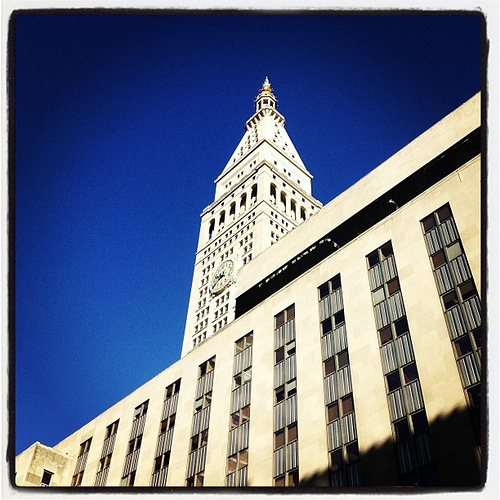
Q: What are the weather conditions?
A: It is clear.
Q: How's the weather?
A: It is clear.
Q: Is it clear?
A: Yes, it is clear.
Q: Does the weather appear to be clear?
A: Yes, it is clear.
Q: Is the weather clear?
A: Yes, it is clear.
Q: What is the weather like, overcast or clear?
A: It is clear.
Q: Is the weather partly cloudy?
A: No, it is clear.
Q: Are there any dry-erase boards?
A: No, there are no dry-erase boards.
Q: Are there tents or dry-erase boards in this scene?
A: No, there are no dry-erase boards or tents.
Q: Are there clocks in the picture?
A: Yes, there is a clock.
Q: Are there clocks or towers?
A: Yes, there is a clock.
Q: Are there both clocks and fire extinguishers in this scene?
A: No, there is a clock but no fire extinguishers.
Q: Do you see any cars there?
A: No, there are no cars.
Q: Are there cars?
A: No, there are no cars.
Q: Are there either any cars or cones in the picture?
A: No, there are no cars or cones.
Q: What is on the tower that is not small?
A: The clock is on the tower.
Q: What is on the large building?
A: The clock is on the tower.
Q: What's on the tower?
A: The clock is on the tower.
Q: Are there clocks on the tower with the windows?
A: Yes, there is a clock on the tower.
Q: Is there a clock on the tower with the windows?
A: Yes, there is a clock on the tower.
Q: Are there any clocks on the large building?
A: Yes, there is a clock on the tower.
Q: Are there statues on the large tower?
A: No, there is a clock on the tower.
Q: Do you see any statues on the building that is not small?
A: No, there is a clock on the tower.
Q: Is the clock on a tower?
A: Yes, the clock is on a tower.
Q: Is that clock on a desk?
A: No, the clock is on a tower.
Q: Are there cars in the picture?
A: No, there are no cars.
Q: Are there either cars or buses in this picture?
A: No, there are no cars or buses.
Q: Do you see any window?
A: Yes, there are windows.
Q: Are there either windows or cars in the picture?
A: Yes, there are windows.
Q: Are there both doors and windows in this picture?
A: No, there are windows but no doors.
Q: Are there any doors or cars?
A: No, there are no cars or doors.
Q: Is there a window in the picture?
A: Yes, there are windows.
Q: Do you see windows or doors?
A: Yes, there are windows.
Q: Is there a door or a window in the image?
A: Yes, there are windows.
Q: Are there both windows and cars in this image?
A: No, there are windows but no cars.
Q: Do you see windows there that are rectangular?
A: Yes, there are rectangular windows.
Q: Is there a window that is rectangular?
A: Yes, there are windows that are rectangular.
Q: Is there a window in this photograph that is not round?
A: Yes, there are rectangular windows.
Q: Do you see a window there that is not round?
A: Yes, there are rectangular windows.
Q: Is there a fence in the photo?
A: No, there are no fences.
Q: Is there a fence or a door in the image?
A: No, there are no fences or doors.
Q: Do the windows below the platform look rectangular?
A: Yes, the windows are rectangular.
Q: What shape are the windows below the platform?
A: The windows are rectangular.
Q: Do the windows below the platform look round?
A: No, the windows are rectangular.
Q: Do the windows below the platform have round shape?
A: No, the windows are rectangular.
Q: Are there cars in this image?
A: No, there are no cars.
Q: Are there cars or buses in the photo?
A: No, there are no cars or buses.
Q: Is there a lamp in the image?
A: No, there are no lamps.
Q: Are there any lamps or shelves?
A: No, there are no lamps or shelves.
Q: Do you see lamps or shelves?
A: No, there are no lamps or shelves.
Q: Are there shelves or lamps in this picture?
A: No, there are no lamps or shelves.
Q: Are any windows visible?
A: Yes, there is a window.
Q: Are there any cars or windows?
A: Yes, there is a window.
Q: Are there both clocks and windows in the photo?
A: Yes, there are both a window and a clock.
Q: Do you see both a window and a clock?
A: Yes, there are both a window and a clock.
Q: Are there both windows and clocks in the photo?
A: Yes, there are both a window and a clock.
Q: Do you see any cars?
A: No, there are no cars.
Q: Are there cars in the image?
A: No, there are no cars.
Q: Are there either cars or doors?
A: No, there are no cars or doors.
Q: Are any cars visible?
A: No, there are no cars.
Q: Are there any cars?
A: No, there are no cars.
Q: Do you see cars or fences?
A: No, there are no cars or fences.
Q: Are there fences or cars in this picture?
A: No, there are no cars or fences.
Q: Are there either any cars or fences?
A: No, there are no cars or fences.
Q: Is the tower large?
A: Yes, the tower is large.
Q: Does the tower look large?
A: Yes, the tower is large.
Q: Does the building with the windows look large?
A: Yes, the tower is large.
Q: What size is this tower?
A: The tower is large.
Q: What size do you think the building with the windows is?
A: The tower is large.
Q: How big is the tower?
A: The tower is large.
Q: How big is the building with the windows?
A: The tower is large.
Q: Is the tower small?
A: No, the tower is large.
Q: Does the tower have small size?
A: No, the tower is large.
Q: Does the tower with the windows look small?
A: No, the tower is large.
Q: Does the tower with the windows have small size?
A: No, the tower is large.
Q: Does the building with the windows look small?
A: No, the tower is large.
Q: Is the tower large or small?
A: The tower is large.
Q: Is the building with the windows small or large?
A: The tower is large.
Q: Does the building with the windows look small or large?
A: The tower is large.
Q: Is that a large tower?
A: Yes, that is a large tower.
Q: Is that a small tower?
A: No, that is a large tower.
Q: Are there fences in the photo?
A: No, there are no fences.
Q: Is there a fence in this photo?
A: No, there are no fences.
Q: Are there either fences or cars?
A: No, there are no fences or cars.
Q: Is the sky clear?
A: Yes, the sky is clear.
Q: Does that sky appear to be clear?
A: Yes, the sky is clear.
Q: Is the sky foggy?
A: No, the sky is clear.